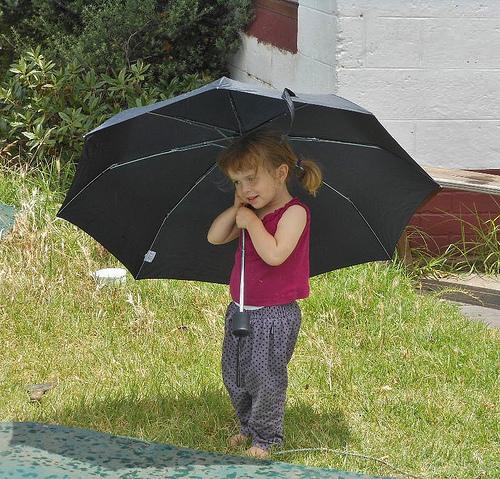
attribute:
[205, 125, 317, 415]
girl — little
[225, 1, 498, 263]
building — brick, white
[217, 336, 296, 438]
legs —  girl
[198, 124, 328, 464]
girl — barefoot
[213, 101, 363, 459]
girl — young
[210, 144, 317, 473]
girl — young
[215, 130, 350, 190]
hair — pigtail style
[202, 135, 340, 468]
girl — arm 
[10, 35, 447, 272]
umbrella — black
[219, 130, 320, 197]
hair — red